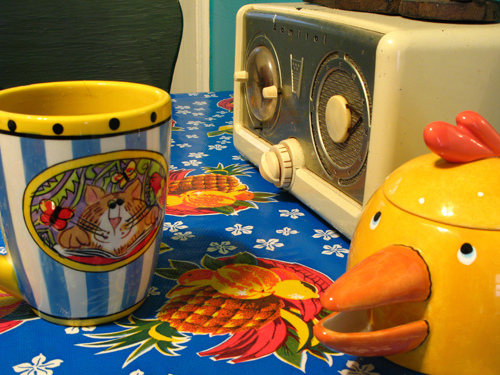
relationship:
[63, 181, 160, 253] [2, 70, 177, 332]
cat colorful cup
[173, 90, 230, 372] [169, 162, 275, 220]
table cloth with fruit designs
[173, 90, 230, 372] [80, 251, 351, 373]
table cloth with fruit designs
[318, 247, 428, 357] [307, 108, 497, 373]
beak shaped jar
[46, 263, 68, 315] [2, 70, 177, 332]
blue and white striped cup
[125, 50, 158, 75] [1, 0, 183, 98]
back of a black chair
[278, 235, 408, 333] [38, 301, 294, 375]
bowl on table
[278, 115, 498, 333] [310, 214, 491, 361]
bowl shaped like a chicken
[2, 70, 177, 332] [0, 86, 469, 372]
cup on table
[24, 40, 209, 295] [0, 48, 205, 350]
cat on cup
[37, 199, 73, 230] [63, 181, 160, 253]
butterfly beside cat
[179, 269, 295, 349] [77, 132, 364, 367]
pineapple on tablecloth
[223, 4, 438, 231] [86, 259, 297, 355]
timer on table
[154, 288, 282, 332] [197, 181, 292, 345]
fruits on table cloth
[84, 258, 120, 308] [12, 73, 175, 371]
blue stripes on cup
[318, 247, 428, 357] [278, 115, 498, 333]
beak on bowl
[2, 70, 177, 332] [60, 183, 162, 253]
cup has a cat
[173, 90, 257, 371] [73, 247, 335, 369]
table cloth has fruit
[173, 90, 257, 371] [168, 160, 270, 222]
table cloth has fruit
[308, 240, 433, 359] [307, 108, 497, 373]
nose on jar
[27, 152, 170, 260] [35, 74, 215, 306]
cartoon on cup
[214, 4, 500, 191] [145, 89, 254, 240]
radio on table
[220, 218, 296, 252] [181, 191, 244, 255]
white flowers on table cloth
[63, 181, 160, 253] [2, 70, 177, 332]
cat on front of cup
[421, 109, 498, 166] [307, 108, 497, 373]
feather on top of jar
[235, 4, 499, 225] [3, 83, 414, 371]
radio on table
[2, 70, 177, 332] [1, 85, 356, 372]
cup on table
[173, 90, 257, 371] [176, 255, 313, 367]
table cloth has fruits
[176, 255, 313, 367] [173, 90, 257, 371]
fruits on table cloth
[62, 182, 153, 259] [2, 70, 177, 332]
dog on cup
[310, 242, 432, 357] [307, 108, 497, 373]
beak of jar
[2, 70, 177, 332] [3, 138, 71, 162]
cup has strips